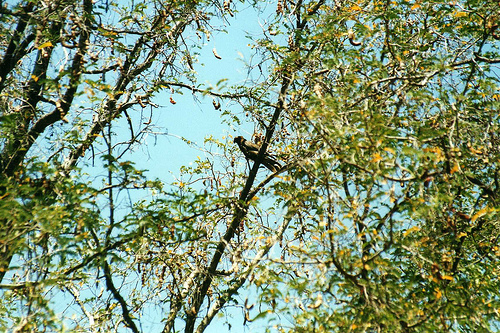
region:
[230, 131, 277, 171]
a black bird in tree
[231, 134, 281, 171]
bird resting on tree branch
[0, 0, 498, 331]
a clear blue sky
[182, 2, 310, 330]
a long tree branch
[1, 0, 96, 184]
a long tree branch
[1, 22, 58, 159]
a long tree branch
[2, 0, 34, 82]
a long tree branch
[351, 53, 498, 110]
a long tree branch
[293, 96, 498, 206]
a long tree branch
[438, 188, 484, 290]
a long tree branch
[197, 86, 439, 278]
a bird in the tree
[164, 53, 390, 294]
a bird on a tree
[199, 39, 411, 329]
a bird standing on a tree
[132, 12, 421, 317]
a small bird on the tree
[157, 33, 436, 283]
a small bird in a tree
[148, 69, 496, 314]
a small bird standing on a tree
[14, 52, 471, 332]
a tree with leaves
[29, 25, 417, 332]
a tree with green leaves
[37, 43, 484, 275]
leaves on a tree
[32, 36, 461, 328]
green leaves on a tree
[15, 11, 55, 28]
Black bird on top of a branch.Black bird on top of a branch.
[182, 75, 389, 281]
a bird is in the trees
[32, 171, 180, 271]
the branches have leaves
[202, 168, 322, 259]
the branches are black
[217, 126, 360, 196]
the black bird is in the tree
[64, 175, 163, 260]
green leaves on the trees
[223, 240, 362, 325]
sun is shining on the leaves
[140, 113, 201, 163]
the sky is cloudy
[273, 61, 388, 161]
the orange leaves on the tree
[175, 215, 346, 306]
white leaves on the tree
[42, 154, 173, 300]
the sun turned the leaves orange